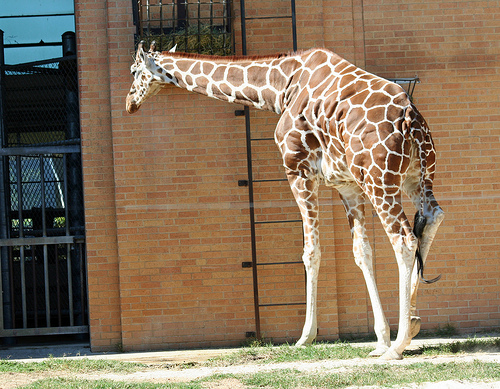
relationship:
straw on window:
[187, 29, 204, 49] [134, 0, 239, 47]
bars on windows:
[132, 2, 222, 41] [131, 0, 236, 62]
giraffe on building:
[124, 39, 446, 359] [76, 4, 484, 346]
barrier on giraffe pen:
[8, 144, 86, 345] [8, 7, 495, 387]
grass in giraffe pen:
[0, 328, 498, 387] [8, 7, 495, 387]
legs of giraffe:
[298, 205, 424, 352] [124, 39, 446, 359]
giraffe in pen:
[124, 39, 446, 359] [2, 2, 498, 386]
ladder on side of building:
[233, 1, 307, 344] [73, 18, 491, 328]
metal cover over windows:
[127, 2, 236, 69] [131, 0, 236, 62]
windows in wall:
[131, 0, 236, 62] [113, 12, 493, 330]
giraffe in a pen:
[124, 39, 446, 359] [2, 2, 498, 386]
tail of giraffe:
[404, 119, 432, 276] [124, 39, 446, 359]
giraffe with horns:
[124, 39, 446, 359] [135, 38, 165, 59]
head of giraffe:
[126, 58, 169, 118] [124, 39, 446, 359]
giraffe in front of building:
[124, 39, 446, 359] [73, 18, 491, 328]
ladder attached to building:
[233, 1, 307, 344] [73, 18, 491, 328]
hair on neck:
[163, 49, 288, 66] [157, 49, 302, 111]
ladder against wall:
[238, 118, 308, 344] [120, 121, 237, 338]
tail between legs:
[404, 119, 432, 276] [381, 156, 421, 357]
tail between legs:
[404, 119, 432, 276] [413, 152, 448, 349]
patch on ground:
[255, 360, 346, 370] [0, 330, 500, 386]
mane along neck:
[158, 47, 307, 66] [162, 49, 292, 113]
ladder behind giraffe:
[233, 1, 307, 344] [124, 39, 446, 359]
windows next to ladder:
[131, 4, 240, 62] [233, 1, 307, 344]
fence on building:
[3, 72, 91, 327] [78, 19, 490, 283]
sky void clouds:
[3, 4, 75, 69] [4, 0, 64, 65]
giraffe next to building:
[124, 39, 446, 359] [76, 4, 484, 346]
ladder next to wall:
[233, 1, 307, 344] [72, 0, 498, 345]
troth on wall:
[135, 19, 230, 57] [72, 0, 498, 345]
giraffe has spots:
[124, 39, 446, 359] [308, 73, 354, 127]